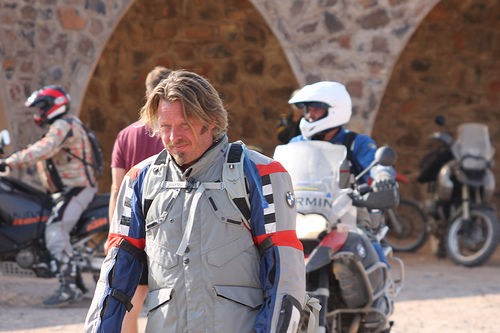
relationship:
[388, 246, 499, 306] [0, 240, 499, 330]
shadow falls on ground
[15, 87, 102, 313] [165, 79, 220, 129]
man with hair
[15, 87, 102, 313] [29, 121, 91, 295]
man with outfit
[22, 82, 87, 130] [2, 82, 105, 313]
helmet on man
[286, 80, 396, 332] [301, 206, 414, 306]
man on motorcycle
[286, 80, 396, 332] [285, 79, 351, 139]
man with helmet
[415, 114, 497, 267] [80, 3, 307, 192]
motorbike near wall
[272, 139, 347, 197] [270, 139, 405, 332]
windshield on motorcycle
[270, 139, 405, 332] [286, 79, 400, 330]
motorcycle ridden by man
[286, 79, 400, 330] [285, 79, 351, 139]
man with helmet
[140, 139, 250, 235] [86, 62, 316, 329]
shoulder straps of man